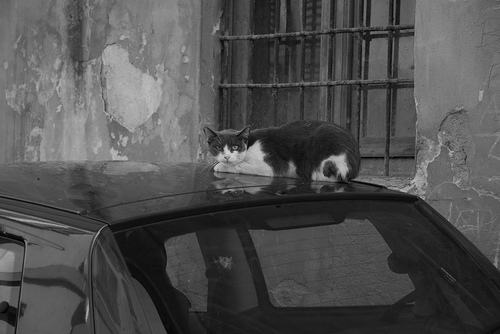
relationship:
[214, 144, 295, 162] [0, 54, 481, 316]
eyes looking camera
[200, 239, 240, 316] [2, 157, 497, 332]
seat belt hanging car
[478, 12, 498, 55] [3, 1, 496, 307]
b etched into wall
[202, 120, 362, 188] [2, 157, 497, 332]
cat on car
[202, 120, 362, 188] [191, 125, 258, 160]
cat has head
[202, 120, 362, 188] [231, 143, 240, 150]
cat has eye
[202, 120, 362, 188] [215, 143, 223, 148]
cat has eye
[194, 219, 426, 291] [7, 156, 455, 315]
windshield on car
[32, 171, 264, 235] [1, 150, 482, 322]
roof top on car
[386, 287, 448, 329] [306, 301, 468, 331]
steering wheel on dashboard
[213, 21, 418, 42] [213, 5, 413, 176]
bars on window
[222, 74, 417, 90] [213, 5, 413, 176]
bars on window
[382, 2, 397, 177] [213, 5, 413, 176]
bars on window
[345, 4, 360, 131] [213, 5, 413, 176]
bars on window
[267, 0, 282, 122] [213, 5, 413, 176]
bars on window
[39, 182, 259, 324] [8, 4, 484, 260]
car next to building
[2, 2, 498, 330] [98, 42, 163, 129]
building have mark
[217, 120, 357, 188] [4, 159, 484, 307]
cat on top of car